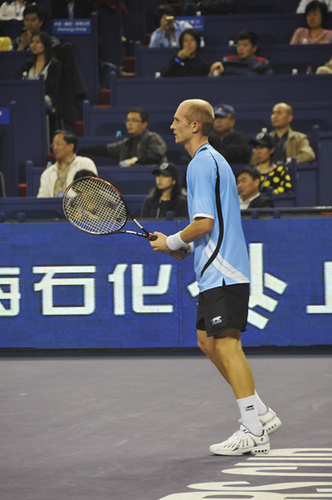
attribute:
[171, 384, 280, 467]
man's shoes — white, black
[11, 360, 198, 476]
ground — gray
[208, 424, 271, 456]
sneakers — white, gray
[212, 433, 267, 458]
sneakers — white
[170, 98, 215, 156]
head — bald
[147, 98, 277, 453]
man — white, orange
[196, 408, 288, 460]
shoes — white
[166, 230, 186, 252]
band — white, wrist band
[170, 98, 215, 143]
head — bald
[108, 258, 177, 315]
writing — white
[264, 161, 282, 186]
shirt — polka dot, black, yellow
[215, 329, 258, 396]
man's leg — tan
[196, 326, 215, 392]
man's leg — tan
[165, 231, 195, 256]
wrist band — white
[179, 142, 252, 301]
jersey — long, blue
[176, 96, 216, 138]
hair — short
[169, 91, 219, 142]
hair — blonde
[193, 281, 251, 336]
shorts — black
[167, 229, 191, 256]
sweatband — white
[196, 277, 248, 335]
shorts — black 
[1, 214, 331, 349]
wall — blue, short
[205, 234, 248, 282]
stripes — white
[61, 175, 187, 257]
racket — black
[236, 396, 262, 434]
sock — white